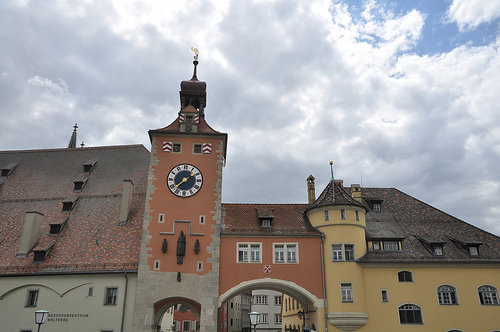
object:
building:
[0, 143, 151, 330]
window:
[397, 270, 405, 282]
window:
[339, 282, 353, 288]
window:
[380, 290, 388, 303]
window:
[197, 260, 204, 273]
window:
[354, 208, 361, 220]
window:
[198, 215, 205, 225]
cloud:
[0, 0, 499, 237]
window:
[339, 209, 346, 220]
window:
[397, 309, 408, 324]